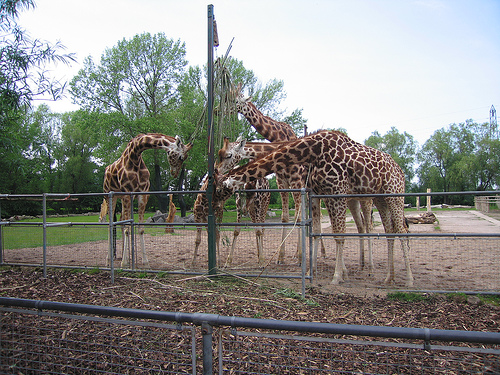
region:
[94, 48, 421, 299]
A herd of giraffes in captivity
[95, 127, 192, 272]
giraffe in a holding pen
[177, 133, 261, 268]
giraffe in a holding pen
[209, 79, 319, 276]
giraffe in a holding pen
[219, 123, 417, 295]
giraffe in a holding pen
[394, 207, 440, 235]
stump lying on the ground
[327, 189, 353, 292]
leg of a giraffe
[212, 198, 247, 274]
leg of a giraffe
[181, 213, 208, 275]
leg of a giraffe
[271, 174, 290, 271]
leg of a giraffe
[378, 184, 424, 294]
leg of a giraffe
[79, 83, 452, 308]
giraffes in an enclosure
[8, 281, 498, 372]
fence of an animal enclosure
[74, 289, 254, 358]
mulch on the ground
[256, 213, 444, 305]
legs of giraffes in an enclosure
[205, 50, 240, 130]
feeding station for giraffes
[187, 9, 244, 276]
metal pole holding giraffe food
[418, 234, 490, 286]
dirt ground by giraffes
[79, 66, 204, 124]
green leaves on trees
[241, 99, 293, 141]
neck of a giraffe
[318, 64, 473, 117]
cloudy sky in the distance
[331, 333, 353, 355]
part of a metal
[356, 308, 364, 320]
part of a groyund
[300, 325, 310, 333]
part of a metal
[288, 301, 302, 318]
part of a geround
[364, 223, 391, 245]
edge of a metal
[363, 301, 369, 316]
part of a ground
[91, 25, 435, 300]
A herd of giraffe in captivity